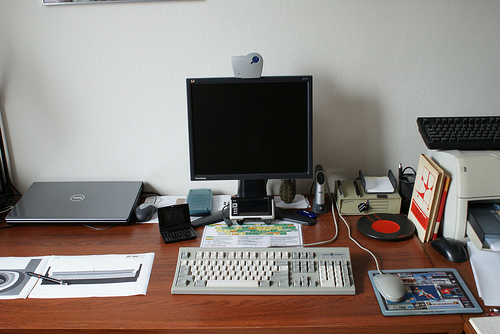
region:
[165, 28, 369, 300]
computer on a wooden desk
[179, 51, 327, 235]
black computer monitor on a desk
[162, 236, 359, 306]
grey computer keyboard on a desk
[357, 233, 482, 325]
grey mouse and mousepad on a desk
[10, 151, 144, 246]
laptop on a wooden desk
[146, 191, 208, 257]
miniature laptop on a wooden desk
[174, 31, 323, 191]
web camera on top of a computer monitor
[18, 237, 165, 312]
black pen sitting on paper on a desk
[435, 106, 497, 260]
computer printer on a desk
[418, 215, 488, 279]
black computer mouse on a desk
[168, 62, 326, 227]
Monitor for a desktop computer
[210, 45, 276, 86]
Webcam on top of the monitor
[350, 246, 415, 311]
Grey mouse for the computer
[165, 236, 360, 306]
Grey keyboard for a computer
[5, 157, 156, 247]
Closed grey laptop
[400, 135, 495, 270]
White printer with paper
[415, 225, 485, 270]
Black computer mouse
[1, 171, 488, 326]
Wood computer desk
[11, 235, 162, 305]
Notebook and pen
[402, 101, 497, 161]
Black keyboard sitting on the printer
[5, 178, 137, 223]
Closed Dell laptop computer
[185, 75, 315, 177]
Flatscreen desktop computer monitor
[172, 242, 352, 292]
Grey and white desktop computer keyboard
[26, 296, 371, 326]
top of wood desk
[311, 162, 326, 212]
Small grey computer webcam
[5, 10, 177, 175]
Flat white painted interior wall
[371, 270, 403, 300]
Desktop computer mouse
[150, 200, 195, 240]
Black electronic day planner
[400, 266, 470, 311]
Computer mouse pad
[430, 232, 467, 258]
Black computer mouse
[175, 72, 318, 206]
a small black monitor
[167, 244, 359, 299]
a white and grey computer keyboard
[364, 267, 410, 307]
a grey corded mouse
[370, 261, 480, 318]
a mouse pad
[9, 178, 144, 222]
a closed laptop computer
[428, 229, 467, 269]
a black computer mouse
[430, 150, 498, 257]
a white inkjet printer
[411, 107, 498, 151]
a black computer keyboard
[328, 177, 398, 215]
a KVM switch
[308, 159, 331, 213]
a silver and black router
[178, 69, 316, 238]
computer on wood desk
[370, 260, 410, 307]
mouse on mouse pad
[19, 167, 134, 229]
lap top on desk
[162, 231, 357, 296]
key board on desk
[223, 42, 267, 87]
web cam on computer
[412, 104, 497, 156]
black keyboard on printer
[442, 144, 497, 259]
printer on corner of desk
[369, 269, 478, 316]
colorful mouse pad on desk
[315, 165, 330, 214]
hard drive on desk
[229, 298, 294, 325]
wood surface of desk